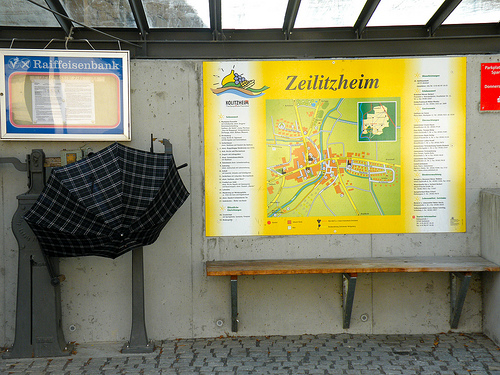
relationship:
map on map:
[259, 90, 411, 232] [202, 60, 473, 235]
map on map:
[259, 90, 404, 217] [259, 90, 411, 232]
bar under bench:
[449, 270, 476, 331] [206, 251, 494, 281]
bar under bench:
[337, 268, 357, 330] [206, 251, 494, 281]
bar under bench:
[227, 277, 239, 331] [206, 251, 494, 281]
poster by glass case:
[4, 55, 126, 137] [0, 47, 136, 144]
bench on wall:
[201, 173, 495, 281] [41, 54, 472, 281]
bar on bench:
[227, 277, 239, 331] [203, 255, 498, 274]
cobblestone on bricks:
[180, 352, 196, 362] [230, 348, 247, 357]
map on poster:
[210, 60, 471, 249] [4, 55, 126, 137]